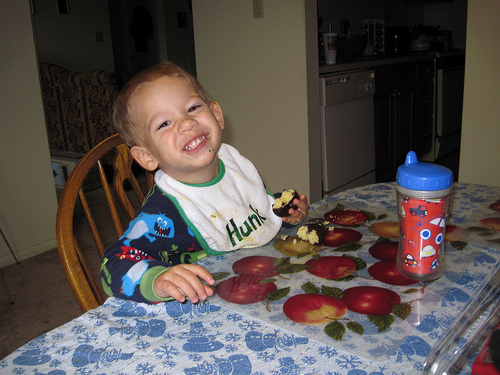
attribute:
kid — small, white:
[96, 54, 286, 303]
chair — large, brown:
[55, 131, 154, 308]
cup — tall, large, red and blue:
[393, 145, 459, 273]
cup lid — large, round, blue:
[393, 148, 457, 194]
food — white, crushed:
[270, 185, 306, 218]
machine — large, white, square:
[319, 68, 381, 194]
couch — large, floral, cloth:
[37, 60, 123, 163]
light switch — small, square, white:
[249, 0, 267, 21]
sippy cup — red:
[395, 147, 455, 276]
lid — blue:
[393, 145, 454, 190]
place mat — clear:
[187, 201, 468, 367]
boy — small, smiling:
[99, 60, 309, 310]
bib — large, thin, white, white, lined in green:
[154, 141, 284, 251]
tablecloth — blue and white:
[1, 183, 499, 370]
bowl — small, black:
[272, 187, 302, 218]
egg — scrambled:
[270, 186, 324, 243]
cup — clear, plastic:
[399, 185, 448, 277]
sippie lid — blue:
[402, 150, 454, 190]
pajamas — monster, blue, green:
[99, 172, 208, 318]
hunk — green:
[224, 204, 270, 245]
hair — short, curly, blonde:
[111, 56, 211, 145]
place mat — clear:
[195, 200, 489, 358]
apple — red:
[288, 287, 400, 322]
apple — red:
[305, 252, 361, 280]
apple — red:
[319, 207, 368, 250]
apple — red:
[222, 250, 283, 301]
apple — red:
[370, 233, 416, 283]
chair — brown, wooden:
[57, 133, 157, 323]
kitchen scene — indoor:
[2, 1, 499, 371]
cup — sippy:
[395, 149, 455, 282]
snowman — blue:
[71, 343, 137, 365]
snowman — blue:
[180, 319, 224, 350]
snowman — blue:
[244, 328, 310, 352]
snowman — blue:
[182, 352, 252, 372]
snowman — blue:
[110, 315, 166, 336]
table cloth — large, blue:
[0, 179, 499, 372]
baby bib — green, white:
[154, 142, 285, 254]